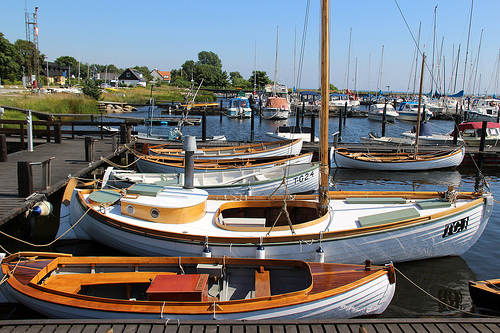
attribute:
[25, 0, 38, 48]
metal tower — tall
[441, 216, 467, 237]
sign — black, white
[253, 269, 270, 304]
bench — wooden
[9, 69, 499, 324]
boats — numerous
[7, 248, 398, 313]
boat — wooden, small, fishing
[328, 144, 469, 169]
boat — white, blue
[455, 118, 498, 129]
cover — burgundy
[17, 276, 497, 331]
dock — wooden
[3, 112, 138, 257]
pier — wooden